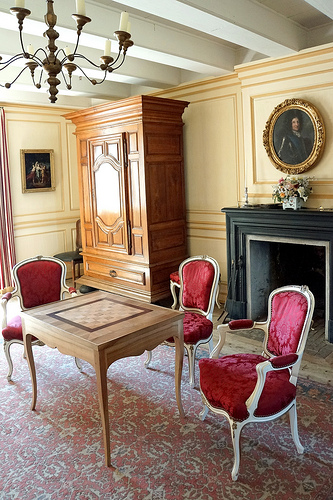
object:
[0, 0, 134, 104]
chandelier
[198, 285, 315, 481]
chairs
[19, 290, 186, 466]
checkers table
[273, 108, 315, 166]
picture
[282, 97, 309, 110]
gold frame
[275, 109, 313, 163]
man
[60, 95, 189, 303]
wood cabinet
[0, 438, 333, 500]
carpet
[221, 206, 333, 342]
fireplace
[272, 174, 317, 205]
flowers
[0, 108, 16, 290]
curtain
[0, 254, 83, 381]
chair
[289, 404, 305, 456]
leg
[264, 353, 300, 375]
arm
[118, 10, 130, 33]
candles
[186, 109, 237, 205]
wall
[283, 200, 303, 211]
vase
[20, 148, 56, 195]
square frame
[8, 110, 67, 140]
wall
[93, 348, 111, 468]
legs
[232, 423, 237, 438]
gold leaf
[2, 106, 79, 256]
gold trim